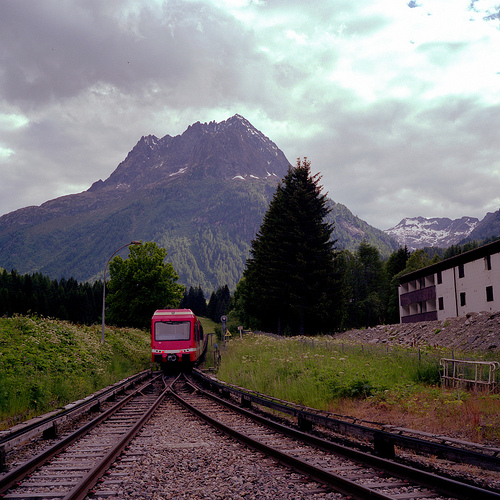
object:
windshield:
[155, 321, 191, 341]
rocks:
[133, 453, 277, 480]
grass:
[0, 308, 152, 429]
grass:
[213, 325, 498, 443]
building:
[396, 239, 500, 325]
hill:
[335, 309, 498, 353]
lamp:
[101, 240, 142, 344]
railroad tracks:
[0, 366, 499, 499]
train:
[150, 308, 214, 370]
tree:
[243, 156, 342, 335]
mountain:
[0, 113, 499, 303]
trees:
[1, 240, 233, 330]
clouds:
[0, 0, 245, 207]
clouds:
[238, 0, 500, 232]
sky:
[0, 0, 500, 206]